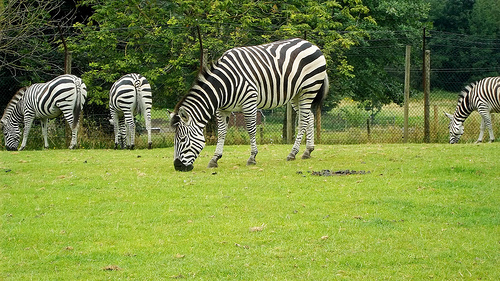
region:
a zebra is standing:
[168, 37, 333, 170]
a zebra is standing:
[105, 67, 154, 152]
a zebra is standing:
[1, 72, 88, 147]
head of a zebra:
[170, 109, 208, 170]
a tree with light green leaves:
[63, 3, 366, 128]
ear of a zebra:
[178, 109, 188, 122]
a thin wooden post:
[403, 44, 411, 148]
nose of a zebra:
[173, 158, 185, 170]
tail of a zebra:
[70, 78, 80, 124]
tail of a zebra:
[133, 78, 143, 127]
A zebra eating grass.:
[169, 35, 329, 170]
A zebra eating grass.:
[1, 71, 88, 150]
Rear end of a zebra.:
[108, 72, 153, 150]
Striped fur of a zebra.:
[244, 49, 289, 99]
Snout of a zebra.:
[174, 145, 197, 169]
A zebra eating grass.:
[446, 75, 498, 143]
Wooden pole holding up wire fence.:
[401, 43, 413, 143]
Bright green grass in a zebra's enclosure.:
[3, 142, 498, 278]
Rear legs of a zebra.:
[288, 55, 328, 162]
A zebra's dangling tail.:
[72, 78, 82, 130]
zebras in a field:
[66, 38, 473, 193]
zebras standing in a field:
[72, 23, 429, 275]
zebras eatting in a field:
[29, 26, 362, 278]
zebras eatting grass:
[19, 12, 458, 274]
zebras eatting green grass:
[75, 43, 493, 215]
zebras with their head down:
[36, 41, 489, 228]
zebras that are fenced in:
[46, 43, 466, 256]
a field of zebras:
[59, 43, 337, 274]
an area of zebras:
[72, 33, 490, 246]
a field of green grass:
[171, 148, 491, 265]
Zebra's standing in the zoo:
[1, 10, 498, 272]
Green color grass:
[283, 180, 435, 252]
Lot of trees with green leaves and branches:
[66, 5, 483, 44]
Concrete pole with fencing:
[329, 34, 496, 137]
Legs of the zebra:
[206, 119, 332, 169]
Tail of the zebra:
[73, 76, 88, 128]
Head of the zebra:
[160, 106, 208, 169]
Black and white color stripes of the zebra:
[240, 54, 301, 94]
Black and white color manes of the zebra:
[176, 55, 216, 105]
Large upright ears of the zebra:
[162, 106, 189, 121]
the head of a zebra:
[153, 88, 231, 185]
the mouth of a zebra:
[164, 154, 204, 176]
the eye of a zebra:
[172, 129, 196, 156]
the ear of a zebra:
[161, 100, 193, 130]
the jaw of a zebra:
[188, 127, 215, 167]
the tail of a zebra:
[296, 30, 356, 126]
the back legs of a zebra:
[268, 80, 351, 177]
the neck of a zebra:
[176, 67, 238, 126]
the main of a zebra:
[160, 45, 219, 122]